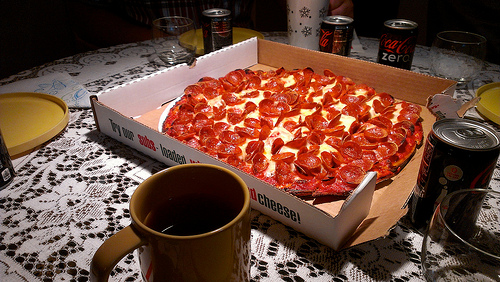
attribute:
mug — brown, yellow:
[89, 161, 253, 281]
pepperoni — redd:
[258, 99, 281, 117]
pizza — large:
[157, 67, 425, 200]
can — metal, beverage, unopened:
[406, 118, 498, 241]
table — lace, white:
[0, 23, 498, 280]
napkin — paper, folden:
[3, 69, 93, 108]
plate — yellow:
[0, 92, 70, 162]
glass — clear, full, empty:
[151, 15, 199, 65]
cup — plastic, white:
[287, 0, 330, 52]